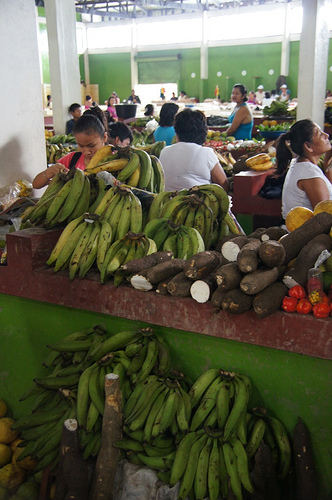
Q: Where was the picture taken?
A: It was taken at the market.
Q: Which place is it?
A: It is a market.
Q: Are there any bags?
A: No, there are no bags.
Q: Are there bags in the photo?
A: No, there are no bags.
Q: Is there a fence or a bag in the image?
A: No, there are no bags or fences.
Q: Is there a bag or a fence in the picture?
A: No, there are no bags or fences.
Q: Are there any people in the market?
A: Yes, there is a person in the market.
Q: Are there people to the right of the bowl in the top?
A: Yes, there is a person to the right of the bowl.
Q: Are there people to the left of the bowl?
A: No, the person is to the right of the bowl.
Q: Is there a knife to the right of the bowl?
A: No, there is a person to the right of the bowl.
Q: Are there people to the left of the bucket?
A: No, the person is to the right of the bucket.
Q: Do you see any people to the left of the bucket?
A: No, the person is to the right of the bucket.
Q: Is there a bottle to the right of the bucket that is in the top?
A: No, there is a person to the right of the bucket.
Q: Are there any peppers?
A: Yes, there are peppers.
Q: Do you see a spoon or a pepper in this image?
A: Yes, there are peppers.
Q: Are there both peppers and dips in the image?
A: No, there are peppers but no dips.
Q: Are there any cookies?
A: No, there are no cookies.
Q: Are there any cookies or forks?
A: No, there are no cookies or forks.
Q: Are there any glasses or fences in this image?
A: No, there are no fences or glasses.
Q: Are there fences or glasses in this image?
A: No, there are no fences or glasses.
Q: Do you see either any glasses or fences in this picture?
A: No, there are no fences or glasses.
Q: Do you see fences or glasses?
A: No, there are no fences or glasses.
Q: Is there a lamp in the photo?
A: No, there are no lamps.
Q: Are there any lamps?
A: No, there are no lamps.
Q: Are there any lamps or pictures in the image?
A: No, there are no lamps or pictures.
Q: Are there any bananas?
A: Yes, there are bananas.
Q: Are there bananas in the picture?
A: Yes, there are bananas.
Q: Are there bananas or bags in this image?
A: Yes, there are bananas.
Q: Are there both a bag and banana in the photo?
A: No, there are bananas but no bags.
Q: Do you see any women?
A: Yes, there is a woman.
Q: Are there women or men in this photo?
A: Yes, there is a woman.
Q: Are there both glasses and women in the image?
A: No, there is a woman but no glasses.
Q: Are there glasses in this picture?
A: No, there are no glasses.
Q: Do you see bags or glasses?
A: No, there are no glasses or bags.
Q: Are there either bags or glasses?
A: No, there are no glasses or bags.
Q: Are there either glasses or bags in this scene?
A: No, there are no glasses or bags.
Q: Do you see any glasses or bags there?
A: No, there are no glasses or bags.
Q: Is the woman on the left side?
A: Yes, the woman is on the left of the image.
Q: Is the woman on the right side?
A: No, the woman is on the left of the image.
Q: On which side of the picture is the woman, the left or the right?
A: The woman is on the left of the image.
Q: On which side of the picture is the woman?
A: The woman is on the left of the image.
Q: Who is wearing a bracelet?
A: The woman is wearing a bracelet.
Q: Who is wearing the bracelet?
A: The woman is wearing a bracelet.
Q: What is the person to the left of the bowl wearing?
A: The woman is wearing a bracelet.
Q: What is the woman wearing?
A: The woman is wearing a bracelet.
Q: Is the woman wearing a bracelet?
A: Yes, the woman is wearing a bracelet.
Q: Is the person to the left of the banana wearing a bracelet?
A: Yes, the woman is wearing a bracelet.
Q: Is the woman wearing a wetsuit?
A: No, the woman is wearing a bracelet.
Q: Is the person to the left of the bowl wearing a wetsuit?
A: No, the woman is wearing a bracelet.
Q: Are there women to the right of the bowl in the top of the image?
A: No, the woman is to the left of the bowl.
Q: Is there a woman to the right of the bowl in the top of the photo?
A: No, the woman is to the left of the bowl.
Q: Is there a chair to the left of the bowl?
A: No, there is a woman to the left of the bowl.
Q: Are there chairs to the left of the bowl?
A: No, there is a woman to the left of the bowl.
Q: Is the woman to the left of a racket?
A: No, the woman is to the left of the bowl.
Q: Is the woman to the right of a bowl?
A: No, the woman is to the left of a bowl.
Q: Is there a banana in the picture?
A: Yes, there is a banana.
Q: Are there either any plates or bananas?
A: Yes, there is a banana.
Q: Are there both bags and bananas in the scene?
A: No, there is a banana but no bags.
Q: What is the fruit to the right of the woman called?
A: The fruit is a banana.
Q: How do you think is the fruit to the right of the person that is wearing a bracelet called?
A: The fruit is a banana.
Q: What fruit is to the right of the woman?
A: The fruit is a banana.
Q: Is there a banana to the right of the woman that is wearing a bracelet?
A: Yes, there is a banana to the right of the woman.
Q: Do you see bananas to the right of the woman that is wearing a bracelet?
A: Yes, there is a banana to the right of the woman.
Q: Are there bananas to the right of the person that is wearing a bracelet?
A: Yes, there is a banana to the right of the woman.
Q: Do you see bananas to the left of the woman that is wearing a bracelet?
A: No, the banana is to the right of the woman.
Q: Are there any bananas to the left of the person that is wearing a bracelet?
A: No, the banana is to the right of the woman.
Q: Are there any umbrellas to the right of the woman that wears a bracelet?
A: No, there is a banana to the right of the woman.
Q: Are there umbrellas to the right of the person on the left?
A: No, there is a banana to the right of the woman.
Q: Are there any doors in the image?
A: Yes, there is a door.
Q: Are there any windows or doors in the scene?
A: Yes, there is a door.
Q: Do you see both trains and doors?
A: No, there is a door but no trains.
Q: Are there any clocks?
A: No, there are no clocks.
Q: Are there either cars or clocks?
A: No, there are no clocks or cars.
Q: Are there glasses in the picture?
A: No, there are no glasses.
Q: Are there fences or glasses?
A: No, there are no glasses or fences.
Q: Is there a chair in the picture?
A: No, there are no chairs.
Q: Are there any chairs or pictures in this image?
A: No, there are no chairs or pictures.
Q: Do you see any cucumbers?
A: No, there are no cucumbers.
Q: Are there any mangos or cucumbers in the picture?
A: No, there are no cucumbers or mangos.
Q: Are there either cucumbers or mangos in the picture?
A: No, there are no cucumbers or mangos.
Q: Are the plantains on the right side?
A: Yes, the plantains are on the right of the image.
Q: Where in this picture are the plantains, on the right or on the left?
A: The plantains are on the right of the image.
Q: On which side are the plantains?
A: The plantains are on the right of the image.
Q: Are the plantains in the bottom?
A: Yes, the plantains are in the bottom of the image.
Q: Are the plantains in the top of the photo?
A: No, the plantains are in the bottom of the image.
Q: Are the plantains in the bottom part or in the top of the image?
A: The plantains are in the bottom of the image.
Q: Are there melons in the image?
A: Yes, there are melons.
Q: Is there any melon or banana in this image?
A: Yes, there are melons.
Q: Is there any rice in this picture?
A: No, there is no rice.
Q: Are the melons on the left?
A: Yes, the melons are on the left of the image.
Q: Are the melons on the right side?
A: No, the melons are on the left of the image.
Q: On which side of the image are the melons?
A: The melons are on the left of the image.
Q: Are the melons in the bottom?
A: Yes, the melons are in the bottom of the image.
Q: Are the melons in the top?
A: No, the melons are in the bottom of the image.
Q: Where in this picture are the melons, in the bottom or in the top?
A: The melons are in the bottom of the image.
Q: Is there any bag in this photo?
A: No, there are no bags.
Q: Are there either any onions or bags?
A: No, there are no bags or onions.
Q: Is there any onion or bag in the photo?
A: No, there are no bags or onions.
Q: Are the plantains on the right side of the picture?
A: Yes, the plantains are on the right of the image.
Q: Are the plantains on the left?
A: No, the plantains are on the right of the image.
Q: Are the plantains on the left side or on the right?
A: The plantains are on the right of the image.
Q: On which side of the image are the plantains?
A: The plantains are on the right of the image.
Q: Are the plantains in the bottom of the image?
A: Yes, the plantains are in the bottom of the image.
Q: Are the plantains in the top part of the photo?
A: No, the plantains are in the bottom of the image.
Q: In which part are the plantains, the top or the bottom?
A: The plantains are in the bottom of the image.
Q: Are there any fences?
A: No, there are no fences.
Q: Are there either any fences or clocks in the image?
A: No, there are no fences or clocks.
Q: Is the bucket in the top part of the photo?
A: Yes, the bucket is in the top of the image.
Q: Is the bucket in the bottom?
A: No, the bucket is in the top of the image.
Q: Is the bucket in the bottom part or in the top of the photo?
A: The bucket is in the top of the image.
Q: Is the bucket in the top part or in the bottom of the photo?
A: The bucket is in the top of the image.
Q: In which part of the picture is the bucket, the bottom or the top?
A: The bucket is in the top of the image.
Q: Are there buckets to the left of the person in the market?
A: Yes, there is a bucket to the left of the person.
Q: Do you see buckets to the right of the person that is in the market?
A: No, the bucket is to the left of the person.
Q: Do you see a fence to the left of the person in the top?
A: No, there is a bucket to the left of the person.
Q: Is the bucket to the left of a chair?
A: No, the bucket is to the left of a person.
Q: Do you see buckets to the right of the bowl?
A: No, the bucket is to the left of the bowl.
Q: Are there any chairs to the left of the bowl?
A: No, there is a bucket to the left of the bowl.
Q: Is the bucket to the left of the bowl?
A: Yes, the bucket is to the left of the bowl.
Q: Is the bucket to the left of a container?
A: No, the bucket is to the left of the bowl.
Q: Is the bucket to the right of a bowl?
A: No, the bucket is to the left of a bowl.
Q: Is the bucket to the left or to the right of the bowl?
A: The bucket is to the left of the bowl.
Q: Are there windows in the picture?
A: Yes, there are windows.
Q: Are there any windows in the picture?
A: Yes, there are windows.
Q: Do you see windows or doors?
A: Yes, there are windows.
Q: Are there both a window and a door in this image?
A: Yes, there are both a window and a door.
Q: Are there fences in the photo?
A: No, there are no fences.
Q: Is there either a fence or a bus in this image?
A: No, there are no fences or buses.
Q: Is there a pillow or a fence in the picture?
A: No, there are no fences or pillows.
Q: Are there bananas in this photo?
A: Yes, there are bananas.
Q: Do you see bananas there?
A: Yes, there are bananas.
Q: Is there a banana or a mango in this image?
A: Yes, there are bananas.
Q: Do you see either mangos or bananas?
A: Yes, there are bananas.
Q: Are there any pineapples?
A: No, there are no pineapples.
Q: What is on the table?
A: The bananas are on the table.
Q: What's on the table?
A: The bananas are on the table.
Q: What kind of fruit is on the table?
A: The fruits are bananas.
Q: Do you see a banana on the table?
A: Yes, there are bananas on the table.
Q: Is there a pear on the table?
A: No, there are bananas on the table.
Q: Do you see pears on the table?
A: No, there are bananas on the table.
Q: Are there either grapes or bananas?
A: Yes, there are bananas.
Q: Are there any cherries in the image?
A: No, there are no cherries.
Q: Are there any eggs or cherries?
A: No, there are no cherries or eggs.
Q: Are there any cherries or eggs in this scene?
A: No, there are no cherries or eggs.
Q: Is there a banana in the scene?
A: Yes, there are bananas.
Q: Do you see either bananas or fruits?
A: Yes, there are bananas.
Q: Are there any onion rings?
A: No, there are no onion rings.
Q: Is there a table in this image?
A: Yes, there is a table.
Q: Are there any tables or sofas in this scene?
A: Yes, there is a table.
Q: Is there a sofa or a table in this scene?
A: Yes, there is a table.